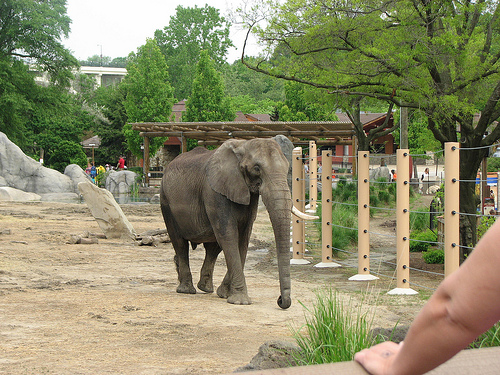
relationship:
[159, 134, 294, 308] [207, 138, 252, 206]
elephant has ear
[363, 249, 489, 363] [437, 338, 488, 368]
person's arm on fence